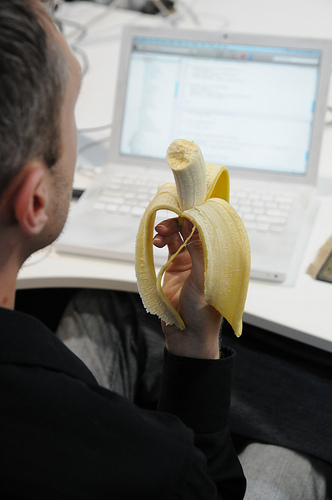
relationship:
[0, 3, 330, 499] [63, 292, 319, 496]
gentleman has crossed legs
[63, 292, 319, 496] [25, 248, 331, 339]
crossed legs under table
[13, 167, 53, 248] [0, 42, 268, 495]
ear of man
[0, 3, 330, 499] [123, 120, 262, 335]
gentleman holding banana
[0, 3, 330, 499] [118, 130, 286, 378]
gentleman holding banana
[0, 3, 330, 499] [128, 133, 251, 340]
gentleman eating banana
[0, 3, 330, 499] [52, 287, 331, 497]
gentleman wearing jeans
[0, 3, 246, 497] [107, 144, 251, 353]
gentleman eaten banana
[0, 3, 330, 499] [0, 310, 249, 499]
gentleman wearing black jacket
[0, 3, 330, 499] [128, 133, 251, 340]
gentleman holding banana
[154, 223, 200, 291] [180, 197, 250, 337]
string coming off a banana peel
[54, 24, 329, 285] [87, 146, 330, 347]
laptop on desk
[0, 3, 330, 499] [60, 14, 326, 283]
gentleman looking at computer